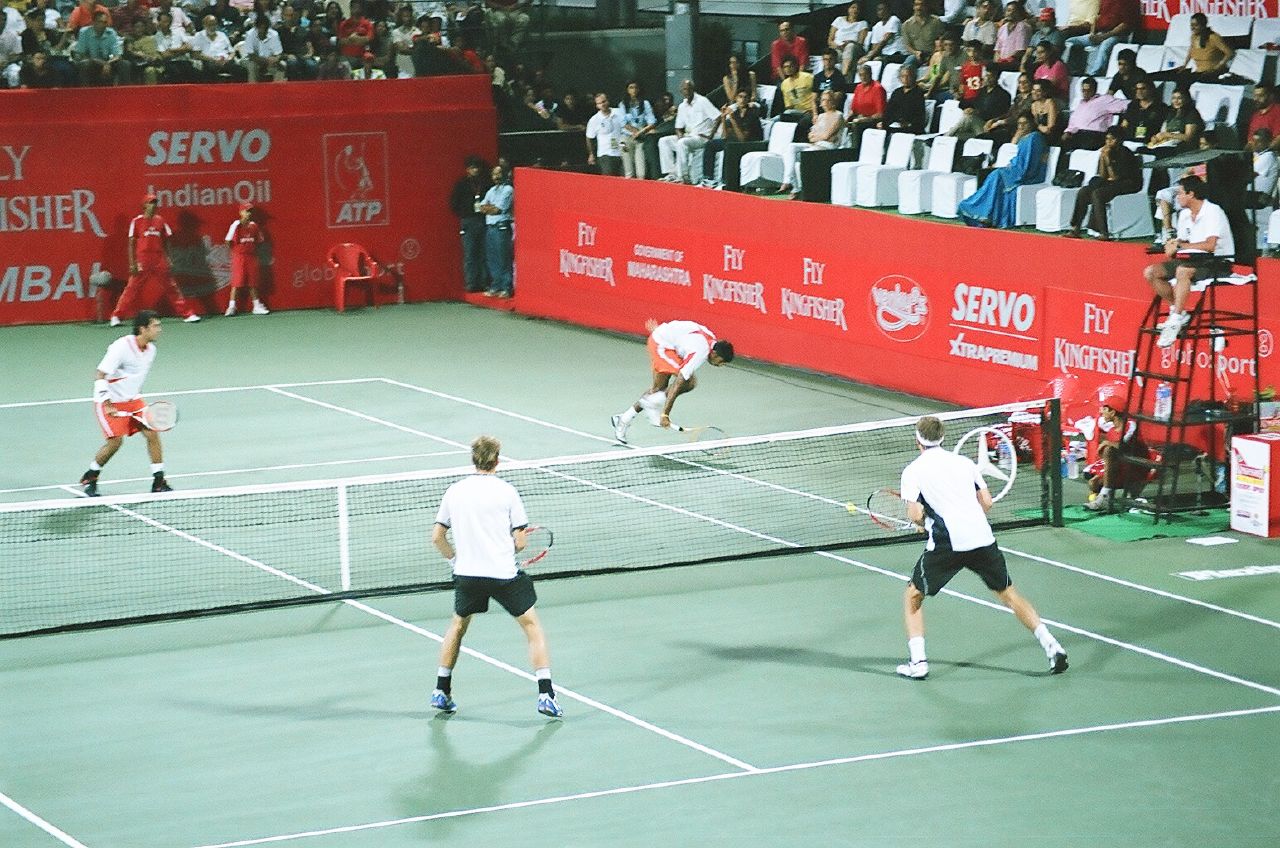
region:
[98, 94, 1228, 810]
the people are playing tennis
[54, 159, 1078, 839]
this is a sporting event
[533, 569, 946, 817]
this is a tennis court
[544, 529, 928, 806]
the court is green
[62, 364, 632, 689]
this is a net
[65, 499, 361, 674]
the net is black and white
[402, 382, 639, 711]
the man is wearing shorts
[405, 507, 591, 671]
the shorts are black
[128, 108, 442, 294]
the wall is red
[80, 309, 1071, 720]
the men are playing tennis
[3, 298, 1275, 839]
the white lines on the green floor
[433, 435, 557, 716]
the man wearing black shorts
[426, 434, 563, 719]
the man wearing a white shirt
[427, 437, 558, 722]
the man carrying the racket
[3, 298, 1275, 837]
the net on the tennis court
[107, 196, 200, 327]
the man standing with his legs far apart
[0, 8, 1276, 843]
the people watching the men play tennis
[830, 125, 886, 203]
the chair is white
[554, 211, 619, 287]
White logo on red banner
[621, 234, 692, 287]
White logo on red banner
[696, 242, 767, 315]
White logo on red banner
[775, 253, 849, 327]
White logo on red banner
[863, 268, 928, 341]
White logo on red banner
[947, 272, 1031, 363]
White logo on red banner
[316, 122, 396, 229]
White logo on red banner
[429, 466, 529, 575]
Man is wearing a white shirt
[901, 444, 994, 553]
Man is wearing a white shirt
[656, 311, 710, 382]
Man is wearing a white shirt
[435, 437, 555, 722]
a tennis player with a white shirt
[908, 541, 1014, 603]
the black shorts of a tennis player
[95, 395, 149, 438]
a pair of red shorts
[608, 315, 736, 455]
a tennis player who is diving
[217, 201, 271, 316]
a ball boy with red clothing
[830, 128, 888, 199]
a white chair in the stadium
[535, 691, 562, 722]
the shoe of a tennis player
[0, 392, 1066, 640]
the net of a tennis court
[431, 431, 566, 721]
player in white top and black short holds racket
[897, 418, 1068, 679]
player in white headband and white shoes holds racket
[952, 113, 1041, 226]
woman in long blue dress on white chair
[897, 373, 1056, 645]
Man holding an orange.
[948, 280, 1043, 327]
large white letters on sign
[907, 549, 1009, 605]
black shorts on man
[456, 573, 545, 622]
black shorts on man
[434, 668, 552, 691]
black socks on man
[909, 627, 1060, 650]
white socks on man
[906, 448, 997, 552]
black and white shirt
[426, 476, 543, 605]
black and white shirt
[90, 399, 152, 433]
orange shorts on man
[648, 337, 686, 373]
orange shorts on man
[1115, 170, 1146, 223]
a person watching the match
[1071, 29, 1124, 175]
a person watching the match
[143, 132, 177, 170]
white letter on sign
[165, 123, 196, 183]
white letter on sign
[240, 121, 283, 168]
white letter on sign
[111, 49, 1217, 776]
this is a sporting event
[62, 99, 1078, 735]
this is a tennis court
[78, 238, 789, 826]
the court is clay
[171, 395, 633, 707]
this is a net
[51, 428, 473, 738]
the net is white and black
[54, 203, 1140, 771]
this is a doubles match